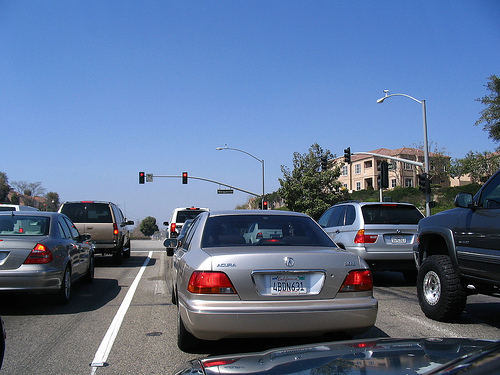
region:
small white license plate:
[250, 271, 321, 308]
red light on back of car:
[175, 259, 238, 302]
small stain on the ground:
[136, 320, 170, 348]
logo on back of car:
[273, 250, 305, 270]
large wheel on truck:
[415, 261, 458, 322]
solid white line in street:
[100, 264, 118, 368]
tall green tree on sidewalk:
[267, 132, 344, 214]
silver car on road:
[166, 199, 363, 320]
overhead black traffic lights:
[114, 155, 266, 211]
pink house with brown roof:
[341, 143, 407, 193]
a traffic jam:
[0, 96, 499, 373]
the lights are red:
[131, 157, 238, 197]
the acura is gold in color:
[175, 211, 384, 358]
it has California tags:
[183, 205, 380, 325]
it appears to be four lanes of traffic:
[2, 157, 496, 373]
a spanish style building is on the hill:
[313, 130, 436, 197]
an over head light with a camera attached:
[364, 85, 449, 130]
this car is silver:
[338, 193, 428, 265]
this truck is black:
[406, 156, 497, 331]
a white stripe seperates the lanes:
[128, 244, 163, 329]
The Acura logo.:
[285, 255, 295, 265]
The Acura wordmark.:
[217, 261, 239, 267]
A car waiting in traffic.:
[172, 335, 498, 373]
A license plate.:
[271, 273, 309, 295]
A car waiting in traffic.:
[163, 210, 378, 349]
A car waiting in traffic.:
[0, 210, 96, 304]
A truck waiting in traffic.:
[411, 167, 498, 323]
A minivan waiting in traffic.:
[315, 202, 425, 283]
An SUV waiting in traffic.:
[57, 199, 134, 261]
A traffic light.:
[138, 171, 144, 182]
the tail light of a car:
[181, 271, 236, 298]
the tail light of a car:
[339, 269, 371, 294]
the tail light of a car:
[24, 243, 52, 267]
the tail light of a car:
[109, 221, 121, 239]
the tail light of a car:
[351, 225, 379, 250]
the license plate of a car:
[261, 271, 321, 300]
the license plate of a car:
[386, 233, 410, 248]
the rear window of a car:
[202, 216, 329, 253]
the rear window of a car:
[359, 201, 424, 228]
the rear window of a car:
[1, 211, 53, 239]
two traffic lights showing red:
[130, 165, 212, 192]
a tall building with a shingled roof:
[331, 132, 446, 186]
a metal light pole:
[361, 72, 446, 191]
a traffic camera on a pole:
[369, 80, 405, 112]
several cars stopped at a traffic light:
[1, 180, 459, 287]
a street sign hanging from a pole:
[206, 177, 248, 204]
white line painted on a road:
[107, 232, 161, 373]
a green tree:
[133, 207, 165, 250]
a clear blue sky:
[101, 44, 348, 141]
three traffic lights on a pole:
[115, 132, 293, 209]